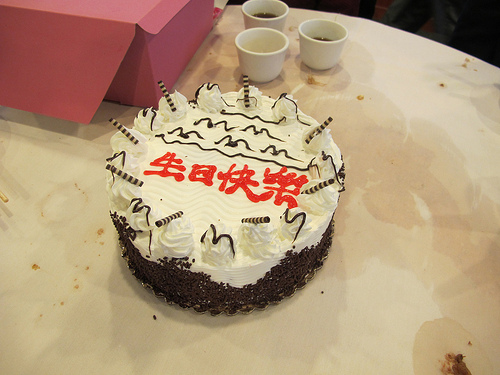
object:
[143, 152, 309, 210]
frosting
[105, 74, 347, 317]
cake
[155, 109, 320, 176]
icing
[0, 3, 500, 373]
tablecloth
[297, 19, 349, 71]
cup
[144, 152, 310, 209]
characters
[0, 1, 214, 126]
box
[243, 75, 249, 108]
biscuit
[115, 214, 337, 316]
cake part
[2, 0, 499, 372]
white ground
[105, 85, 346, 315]
icing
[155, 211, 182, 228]
candle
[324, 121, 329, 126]
striped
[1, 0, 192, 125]
lid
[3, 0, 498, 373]
table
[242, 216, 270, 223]
biscuit stick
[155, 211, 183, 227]
biscuit stick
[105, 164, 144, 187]
biscuit stick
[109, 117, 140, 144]
biscuit stick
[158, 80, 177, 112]
biscuit stick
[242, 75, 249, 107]
biscuit stick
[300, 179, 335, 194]
biscuit stick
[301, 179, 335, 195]
candle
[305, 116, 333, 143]
candle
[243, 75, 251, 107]
candle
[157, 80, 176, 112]
candle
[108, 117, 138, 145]
candle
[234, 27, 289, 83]
bowl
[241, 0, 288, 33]
bowl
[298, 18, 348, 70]
bowl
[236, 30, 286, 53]
eye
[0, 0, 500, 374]
shadow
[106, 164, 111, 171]
stripe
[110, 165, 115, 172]
stripe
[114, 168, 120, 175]
stripe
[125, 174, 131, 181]
stripe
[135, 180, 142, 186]
stripe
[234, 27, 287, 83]
cup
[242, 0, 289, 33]
cup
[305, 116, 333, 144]
biscuit stick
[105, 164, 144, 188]
candles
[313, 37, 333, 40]
liquid